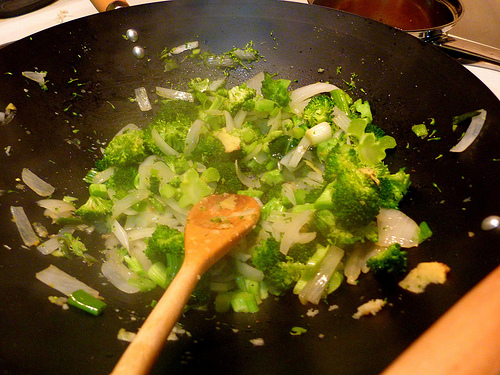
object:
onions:
[36, 239, 58, 254]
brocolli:
[368, 116, 396, 160]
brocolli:
[260, 186, 290, 230]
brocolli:
[228, 98, 277, 129]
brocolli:
[169, 137, 195, 162]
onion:
[15, 161, 54, 195]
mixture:
[206, 156, 259, 191]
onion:
[275, 206, 305, 258]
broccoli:
[303, 167, 389, 248]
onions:
[328, 108, 350, 130]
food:
[70, 64, 431, 321]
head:
[179, 190, 265, 273]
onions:
[168, 215, 183, 228]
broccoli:
[378, 226, 431, 253]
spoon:
[104, 193, 264, 373]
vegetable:
[392, 257, 455, 297]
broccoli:
[146, 222, 189, 288]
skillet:
[4, 3, 484, 373]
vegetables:
[135, 254, 173, 286]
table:
[353, 242, 498, 372]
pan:
[312, 10, 364, 55]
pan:
[350, 37, 413, 55]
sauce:
[328, 7, 437, 47]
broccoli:
[100, 123, 145, 164]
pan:
[331, 320, 375, 367]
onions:
[170, 42, 196, 55]